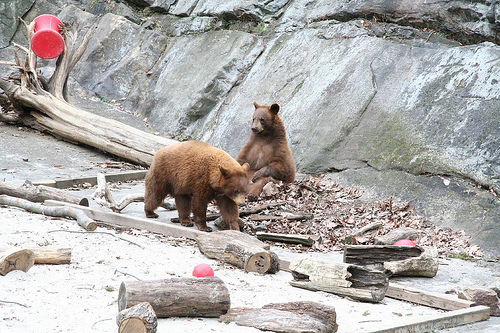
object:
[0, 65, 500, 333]
ground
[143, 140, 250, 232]
bear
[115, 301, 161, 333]
log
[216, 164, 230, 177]
ear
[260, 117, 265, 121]
eye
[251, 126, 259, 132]
nose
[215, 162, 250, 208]
head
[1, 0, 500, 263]
wall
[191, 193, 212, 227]
front legs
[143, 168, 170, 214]
back legs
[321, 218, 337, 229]
leaves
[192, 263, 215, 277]
ball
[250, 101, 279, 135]
head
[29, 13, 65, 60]
basket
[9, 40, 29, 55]
branches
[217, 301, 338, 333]
pieces of wood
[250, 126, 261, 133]
mouth